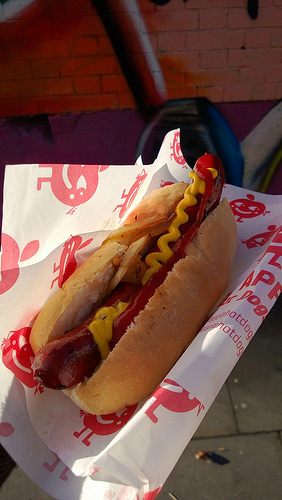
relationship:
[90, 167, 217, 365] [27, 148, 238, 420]
mustard on top of roll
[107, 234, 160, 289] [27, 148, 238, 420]
onions on top of roll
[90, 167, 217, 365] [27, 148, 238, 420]
mustard on roll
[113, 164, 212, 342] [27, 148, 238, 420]
ketchup on roll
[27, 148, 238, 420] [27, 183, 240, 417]
roll on roll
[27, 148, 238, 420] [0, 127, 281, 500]
roll on paper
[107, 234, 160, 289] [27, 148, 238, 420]
onions on roll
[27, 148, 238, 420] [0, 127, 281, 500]
roll sitting on paper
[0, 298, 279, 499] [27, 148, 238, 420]
floor below roll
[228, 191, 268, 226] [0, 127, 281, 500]
logo on paper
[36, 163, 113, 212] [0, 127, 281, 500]
logo on paper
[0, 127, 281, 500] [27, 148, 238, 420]
paper under roll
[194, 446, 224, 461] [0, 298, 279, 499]
leaf on floor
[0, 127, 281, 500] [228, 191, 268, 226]
paper has logo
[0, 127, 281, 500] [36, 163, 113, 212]
paper has logo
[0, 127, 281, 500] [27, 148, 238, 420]
paper around roll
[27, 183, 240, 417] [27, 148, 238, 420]
roll holding roll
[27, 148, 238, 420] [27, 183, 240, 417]
roll in roll